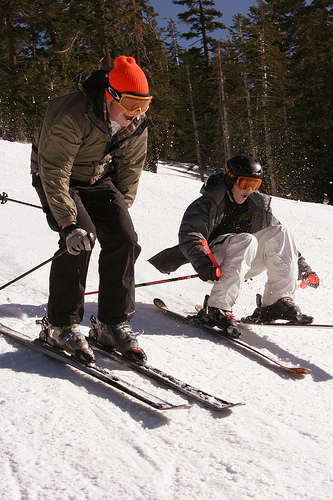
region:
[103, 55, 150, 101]
Beanie is orange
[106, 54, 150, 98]
Goggles around beanie are orange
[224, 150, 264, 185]
Helmet is black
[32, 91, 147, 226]
Jacket is olive green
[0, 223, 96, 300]
Ski pole is black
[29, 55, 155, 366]
Man is skiing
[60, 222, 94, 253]
Hand holding ski pole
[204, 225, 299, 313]
Pants are white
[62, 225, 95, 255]
Glove on hand is gray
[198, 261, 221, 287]
Glove holding orange ski pole is black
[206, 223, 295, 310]
White pants with black zippers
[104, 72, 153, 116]
Black and orange goggles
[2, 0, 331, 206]
Heavily wooded back drop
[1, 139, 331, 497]
Firmly packed snow trail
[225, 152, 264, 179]
Black plastic hard helmet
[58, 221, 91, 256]
Gray and dark gray glove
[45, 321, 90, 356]
Gray and orange ski boot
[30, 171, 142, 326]
Black ski type pants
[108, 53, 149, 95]
Orange knit style cap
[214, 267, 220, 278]
Orange ski pole top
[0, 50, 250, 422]
a man skiing downhill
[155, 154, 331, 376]
a man skiing downhill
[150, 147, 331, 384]
a man crouching on skis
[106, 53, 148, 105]
a bright red winter sock cap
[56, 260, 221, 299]
a black and red ski pole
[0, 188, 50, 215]
a black ski pole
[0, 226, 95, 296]
a black ski pole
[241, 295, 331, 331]
a ski and boot lifted off ground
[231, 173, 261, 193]
orange colored safety glasses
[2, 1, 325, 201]
a group of trees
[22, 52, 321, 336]
two skiiers on the slope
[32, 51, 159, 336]
this skiier is wearing an orange hat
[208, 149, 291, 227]
this skiier has on a helmet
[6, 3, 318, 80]
lots of trees on the slopes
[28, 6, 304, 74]
clear sky in the background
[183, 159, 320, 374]
this boy wearing white pants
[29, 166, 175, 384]
this skiier wearing black pants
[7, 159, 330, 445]
lots of snow on the slopes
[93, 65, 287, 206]
both skiers have on orange goggles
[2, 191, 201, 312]
ski poles to help skiers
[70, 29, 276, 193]
the two skiiers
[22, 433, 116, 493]
the snow on the ground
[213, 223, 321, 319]
the white pants of the skiier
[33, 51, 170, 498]
the skiier with the orange hat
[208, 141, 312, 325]
the skiier with the black helmet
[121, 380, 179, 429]
one of the black ski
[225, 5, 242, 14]
the part of the sky that is showing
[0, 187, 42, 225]
the ski pole of the skiier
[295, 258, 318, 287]
the glove of the skiier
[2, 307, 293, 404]
the skiis of the skiiers